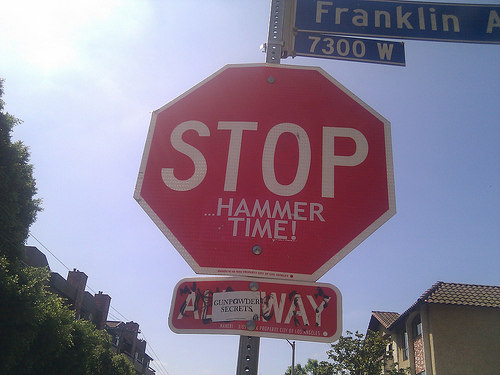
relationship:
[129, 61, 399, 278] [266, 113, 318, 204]
sign has a letter o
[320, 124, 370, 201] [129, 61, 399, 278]
letter has a sign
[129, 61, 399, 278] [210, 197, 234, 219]
sign has a letter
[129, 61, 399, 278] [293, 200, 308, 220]
sign has a letter e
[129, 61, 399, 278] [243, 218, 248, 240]
sign has a letter i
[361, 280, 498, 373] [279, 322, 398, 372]
buildings near tree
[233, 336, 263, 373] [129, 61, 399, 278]
post has sign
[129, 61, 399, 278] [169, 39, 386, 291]
sign has board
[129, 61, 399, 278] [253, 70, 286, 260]
sign has bolts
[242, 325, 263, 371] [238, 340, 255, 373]
pole has holes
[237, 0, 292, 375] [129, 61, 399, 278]
pole has sign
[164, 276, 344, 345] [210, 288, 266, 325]
marks has sticker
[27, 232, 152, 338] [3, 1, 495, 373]
lines are in sky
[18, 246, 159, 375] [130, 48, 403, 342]
building are behind traffic sign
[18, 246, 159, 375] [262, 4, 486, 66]
building are behind address sign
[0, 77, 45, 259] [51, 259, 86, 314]
tree in front of building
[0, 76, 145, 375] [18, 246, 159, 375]
tree in front of building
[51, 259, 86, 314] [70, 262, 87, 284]
building has chimney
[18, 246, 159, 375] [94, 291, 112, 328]
building has chimney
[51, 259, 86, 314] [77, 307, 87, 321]
building has window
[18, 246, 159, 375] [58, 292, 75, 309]
building has window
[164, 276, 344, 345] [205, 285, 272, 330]
marks has sticker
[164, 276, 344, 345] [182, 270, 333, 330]
marks has marks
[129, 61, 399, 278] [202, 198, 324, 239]
sign has words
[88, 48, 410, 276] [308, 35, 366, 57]
sign has 7300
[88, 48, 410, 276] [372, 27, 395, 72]
sign has direction